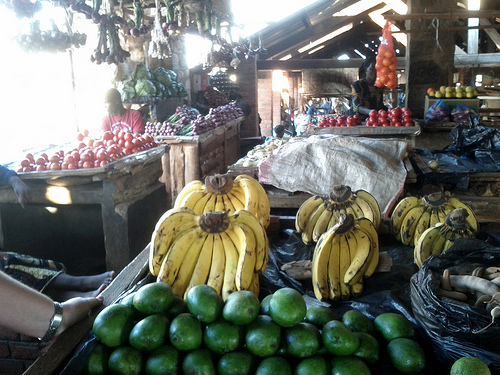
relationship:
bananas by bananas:
[147, 201, 272, 299] [311, 212, 379, 299]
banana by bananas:
[177, 158, 286, 232] [294, 186, 381, 238]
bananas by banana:
[147, 201, 272, 299] [177, 158, 286, 232]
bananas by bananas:
[147, 201, 272, 299] [294, 186, 381, 238]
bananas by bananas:
[147, 201, 272, 299] [171, 167, 273, 217]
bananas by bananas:
[147, 201, 272, 299] [290, 182, 383, 244]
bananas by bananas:
[147, 201, 272, 299] [413, 210, 479, 265]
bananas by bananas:
[147, 201, 272, 299] [388, 185, 478, 245]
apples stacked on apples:
[58, 121, 203, 198] [30, 150, 107, 170]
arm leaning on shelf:
[0, 271, 53, 341] [14, 345, 90, 366]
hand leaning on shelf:
[48, 294, 105, 342] [14, 345, 90, 366]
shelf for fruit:
[111, 271, 139, 287] [43, 169, 491, 374]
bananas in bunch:
[147, 201, 272, 299] [145, 202, 271, 292]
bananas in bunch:
[310, 197, 372, 297] [306, 204, 387, 302]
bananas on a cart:
[291, 185, 326, 249] [268, 179, 368, 334]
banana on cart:
[189, 193, 267, 287] [129, 149, 394, 311]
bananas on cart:
[137, 169, 277, 299] [37, 180, 499, 373]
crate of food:
[11, 109, 199, 219] [38, 113, 216, 198]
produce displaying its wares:
[92, 182, 498, 370] [13, 119, 484, 372]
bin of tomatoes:
[12, 165, 167, 188] [16, 125, 144, 172]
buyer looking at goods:
[349, 56, 388, 116] [316, 104, 414, 128]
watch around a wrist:
[35, 294, 65, 345] [29, 294, 63, 343]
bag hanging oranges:
[374, 19, 397, 89] [375, 19, 398, 89]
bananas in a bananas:
[147, 201, 272, 299] [179, 181, 259, 215]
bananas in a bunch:
[147, 201, 272, 299] [312, 222, 397, 291]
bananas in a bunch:
[147, 201, 272, 299] [399, 204, 449, 246]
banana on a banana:
[230, 219, 256, 291] [142, 210, 189, 277]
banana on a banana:
[230, 219, 256, 291] [302, 227, 330, 302]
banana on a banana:
[230, 219, 256, 291] [205, 232, 227, 296]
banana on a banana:
[230, 219, 256, 291] [234, 174, 259, 215]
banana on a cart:
[230, 219, 256, 291] [37, 180, 499, 373]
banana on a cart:
[230, 219, 256, 291] [0, 96, 250, 278]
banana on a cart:
[230, 219, 256, 291] [223, 136, 413, 212]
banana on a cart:
[230, 219, 256, 291] [305, 104, 420, 149]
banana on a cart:
[230, 219, 256, 291] [405, 123, 498, 224]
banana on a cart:
[177, 158, 286, 232] [37, 180, 499, 373]